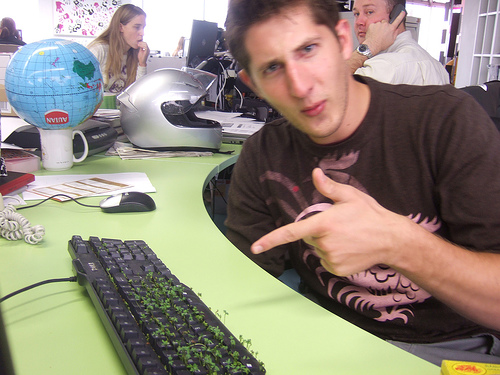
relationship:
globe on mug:
[3, 40, 108, 126] [38, 127, 90, 172]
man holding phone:
[348, 1, 450, 88] [387, 4, 406, 30]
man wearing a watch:
[348, 1, 450, 88] [355, 42, 372, 58]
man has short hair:
[217, 2, 500, 368] [225, 0, 344, 68]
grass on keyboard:
[132, 269, 256, 373] [63, 235, 263, 375]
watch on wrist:
[355, 42, 372, 58] [353, 38, 376, 58]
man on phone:
[348, 1, 450, 88] [387, 4, 406, 30]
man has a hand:
[217, 2, 500, 368] [250, 165, 383, 282]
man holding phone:
[217, 2, 500, 368] [387, 4, 406, 30]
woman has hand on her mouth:
[85, 7, 147, 103] [135, 37, 143, 46]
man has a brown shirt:
[217, 2, 500, 368] [230, 80, 500, 344]